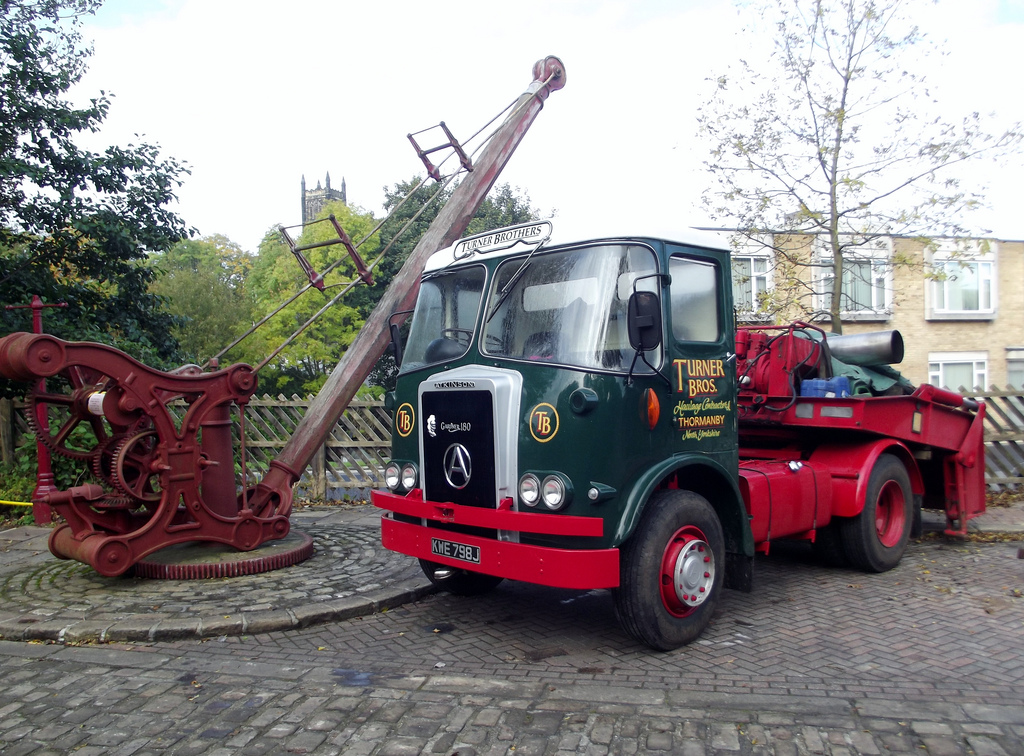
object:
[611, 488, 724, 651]
tire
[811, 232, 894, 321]
window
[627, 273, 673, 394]
side mirror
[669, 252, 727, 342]
window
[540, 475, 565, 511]
light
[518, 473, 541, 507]
light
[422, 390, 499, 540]
grill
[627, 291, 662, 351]
mirror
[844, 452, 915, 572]
tire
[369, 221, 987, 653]
truck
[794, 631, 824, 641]
brick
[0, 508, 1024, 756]
ground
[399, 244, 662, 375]
windshield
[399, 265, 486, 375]
windshield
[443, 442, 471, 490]
logo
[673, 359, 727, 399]
print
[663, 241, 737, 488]
door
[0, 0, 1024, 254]
sky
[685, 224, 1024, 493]
building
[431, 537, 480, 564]
license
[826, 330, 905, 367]
pipe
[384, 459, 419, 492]
headlight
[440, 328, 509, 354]
steering wheel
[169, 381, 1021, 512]
fence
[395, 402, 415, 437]
circle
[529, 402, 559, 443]
circle